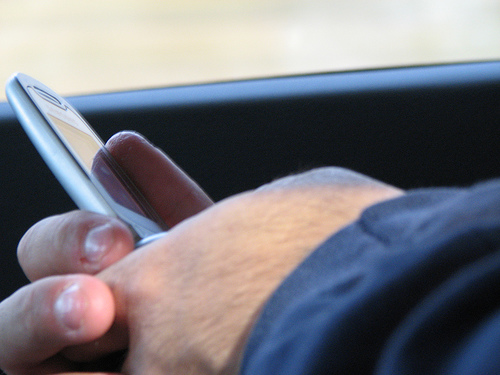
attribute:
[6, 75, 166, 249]
cellphone — outdated, silver, flip, old, use, older, gray, on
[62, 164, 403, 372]
hand — hairy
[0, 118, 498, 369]
man — sitting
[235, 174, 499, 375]
sleeve — blue, gray, grey, long, navy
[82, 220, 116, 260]
fingernails — bitten, short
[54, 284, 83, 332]
fingernails — bitten, short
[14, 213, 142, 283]
finger — clasp, index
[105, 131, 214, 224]
finger — clasp, white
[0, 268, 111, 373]
finger — clasp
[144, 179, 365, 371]
hairy — black, dark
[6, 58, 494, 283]
ledge — black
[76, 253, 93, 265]
wound — small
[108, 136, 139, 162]
skin — dry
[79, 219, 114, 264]
cuticles — sore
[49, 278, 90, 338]
cuticles — sore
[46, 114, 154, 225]
screen — small